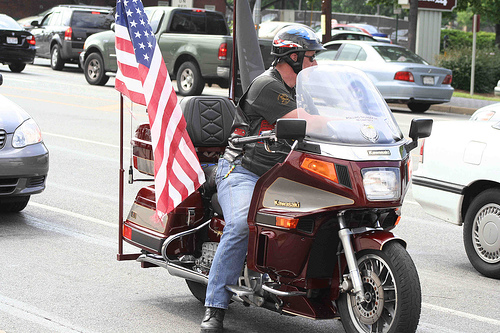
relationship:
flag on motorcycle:
[112, 1, 212, 220] [112, 62, 436, 332]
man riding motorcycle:
[198, 22, 332, 332] [112, 62, 436, 332]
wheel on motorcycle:
[334, 235, 433, 333] [112, 62, 436, 332]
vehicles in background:
[240, 7, 402, 58] [0, 0, 499, 46]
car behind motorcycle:
[0, 71, 51, 218] [112, 62, 436, 332]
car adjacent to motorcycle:
[405, 106, 499, 281] [112, 62, 436, 332]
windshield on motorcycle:
[292, 60, 409, 149] [112, 62, 436, 332]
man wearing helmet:
[198, 22, 332, 332] [266, 23, 327, 76]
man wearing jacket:
[198, 22, 332, 332] [227, 66, 301, 176]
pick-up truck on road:
[77, 5, 277, 99] [0, 56, 499, 332]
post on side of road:
[319, 0, 334, 47] [0, 56, 499, 332]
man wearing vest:
[198, 22, 332, 332] [227, 66, 301, 176]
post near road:
[319, 0, 334, 47] [0, 56, 499, 332]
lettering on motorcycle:
[271, 197, 302, 211] [112, 62, 436, 332]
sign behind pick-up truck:
[166, 0, 195, 12] [77, 5, 277, 99]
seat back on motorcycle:
[172, 93, 244, 150] [112, 62, 436, 332]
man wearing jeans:
[198, 22, 332, 332] [203, 154, 265, 313]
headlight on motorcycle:
[360, 166, 405, 203] [112, 62, 436, 332]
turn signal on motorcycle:
[297, 155, 343, 186] [112, 62, 436, 332]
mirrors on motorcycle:
[274, 117, 307, 151] [112, 62, 436, 332]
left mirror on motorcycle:
[402, 117, 434, 154] [112, 62, 436, 332]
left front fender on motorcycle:
[248, 199, 365, 322] [112, 62, 436, 332]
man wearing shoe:
[198, 22, 332, 332] [200, 304, 229, 333]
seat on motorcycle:
[198, 161, 242, 214] [112, 62, 436, 332]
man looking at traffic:
[198, 22, 332, 332] [0, 0, 483, 114]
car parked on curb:
[308, 37, 455, 116] [388, 101, 484, 117]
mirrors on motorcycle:
[275, 116, 436, 154] [112, 62, 436, 332]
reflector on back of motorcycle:
[117, 223, 139, 243] [112, 62, 436, 332]